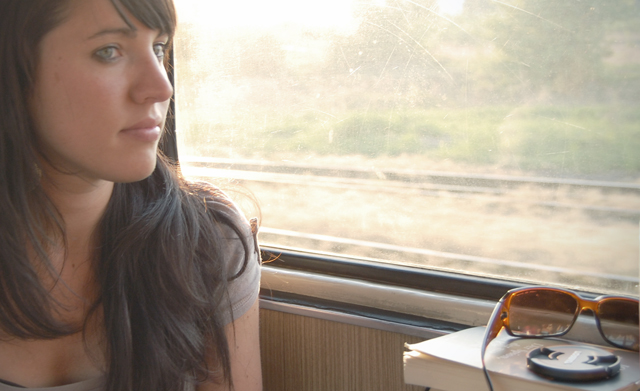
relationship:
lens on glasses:
[602, 297, 620, 343] [483, 286, 640, 390]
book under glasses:
[401, 311, 640, 391] [483, 286, 640, 390]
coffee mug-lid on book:
[524, 340, 622, 382] [401, 311, 640, 391]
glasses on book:
[483, 286, 640, 390] [401, 311, 640, 391]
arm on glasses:
[475, 293, 511, 389] [483, 286, 640, 390]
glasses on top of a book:
[455, 261, 638, 359] [401, 311, 640, 391]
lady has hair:
[0, 1, 253, 388] [63, 8, 239, 389]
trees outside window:
[226, 10, 627, 174] [146, 6, 627, 314]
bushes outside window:
[230, 95, 639, 181] [146, 6, 627, 314]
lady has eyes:
[0, 1, 253, 388] [68, 30, 191, 90]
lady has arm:
[0, 1, 253, 388] [173, 193, 268, 389]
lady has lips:
[0, 1, 253, 388] [97, 115, 186, 149]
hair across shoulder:
[51, 114, 308, 379] [55, 167, 323, 317]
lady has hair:
[0, 1, 253, 388] [51, 114, 308, 379]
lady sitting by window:
[0, 1, 253, 388] [146, 6, 627, 314]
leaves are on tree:
[511, 22, 590, 126] [496, 5, 601, 135]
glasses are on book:
[483, 286, 640, 390] [390, 315, 639, 387]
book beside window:
[401, 311, 640, 391] [126, 6, 632, 294]